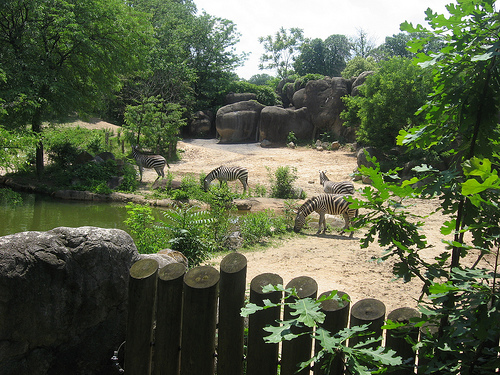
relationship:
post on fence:
[153, 260, 188, 373] [125, 258, 490, 373]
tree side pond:
[0, 0, 157, 179] [0, 187, 288, 239]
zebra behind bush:
[131, 144, 170, 183] [264, 159, 303, 199]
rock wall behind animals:
[201, 75, 399, 151] [126, 145, 397, 239]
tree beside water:
[4, 7, 136, 113] [0, 195, 343, 249]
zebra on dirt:
[292, 193, 360, 239] [3, 117, 485, 367]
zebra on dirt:
[316, 167, 352, 195] [3, 117, 485, 367]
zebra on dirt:
[202, 160, 253, 193] [3, 117, 485, 367]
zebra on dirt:
[121, 143, 169, 181] [3, 117, 485, 367]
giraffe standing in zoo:
[129, 144, 170, 184] [0, 2, 498, 368]